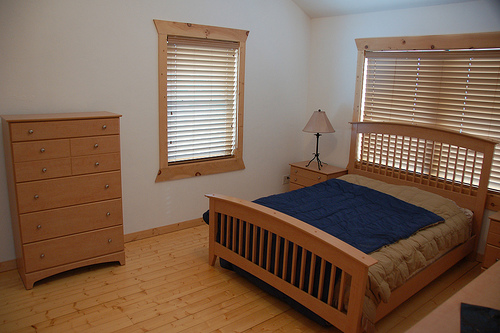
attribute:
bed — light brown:
[205, 123, 497, 331]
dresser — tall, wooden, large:
[7, 111, 127, 289]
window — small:
[165, 35, 240, 163]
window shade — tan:
[168, 34, 238, 167]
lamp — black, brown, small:
[305, 107, 334, 168]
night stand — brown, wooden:
[290, 158, 348, 199]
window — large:
[359, 47, 499, 192]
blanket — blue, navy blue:
[202, 180, 443, 255]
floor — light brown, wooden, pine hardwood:
[1, 220, 485, 332]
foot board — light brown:
[203, 192, 376, 332]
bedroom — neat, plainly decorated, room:
[1, 1, 499, 331]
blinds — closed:
[362, 53, 499, 184]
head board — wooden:
[347, 115, 499, 201]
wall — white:
[1, 2, 356, 262]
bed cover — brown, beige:
[337, 171, 473, 302]